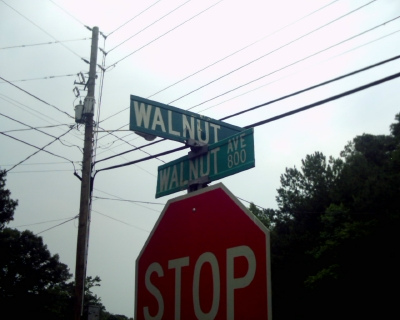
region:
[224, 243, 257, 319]
White P in STOP.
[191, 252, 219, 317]
White O in STOP.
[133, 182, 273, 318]
Red and white stop sign.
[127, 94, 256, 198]
Two green and white WALNUT signs.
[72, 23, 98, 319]
A tall brown wood sign.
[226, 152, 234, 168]
A white 8.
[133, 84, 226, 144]
this is a sign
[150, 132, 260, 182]
this is a sign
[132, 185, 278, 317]
this is a sign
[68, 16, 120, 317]
this is an electricity post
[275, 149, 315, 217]
the is a tree branch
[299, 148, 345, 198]
the is a tree branch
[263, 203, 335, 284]
the is a tree branch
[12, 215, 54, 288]
the is a tree branch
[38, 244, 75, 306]
the is a tree branch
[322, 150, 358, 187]
the is a tree branch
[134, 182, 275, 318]
An octagon red and white stop sign.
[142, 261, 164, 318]
White S in STOP.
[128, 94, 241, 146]
Green and white top sign that says WALNUT.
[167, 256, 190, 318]
White T in STOP.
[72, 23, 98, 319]
A tall brown power pole.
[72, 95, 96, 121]
Transformer buckets up on a brown pole.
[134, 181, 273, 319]
A white and red octagon stop sign.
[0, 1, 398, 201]
Blue and white sky.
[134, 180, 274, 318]
red and white metal stop sign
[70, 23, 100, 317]
wooden power line pole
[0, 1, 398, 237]
high power lines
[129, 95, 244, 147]
green and white street sign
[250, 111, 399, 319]
top of a tall green tree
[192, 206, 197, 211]
small silver bolt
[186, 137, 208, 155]
silver metal sign hardware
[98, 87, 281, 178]
the street sign is green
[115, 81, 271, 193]
the street sign is green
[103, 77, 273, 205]
the street sign is green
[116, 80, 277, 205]
the street sign is green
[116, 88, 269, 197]
the street sign is green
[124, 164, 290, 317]
a red STOP sign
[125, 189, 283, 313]
a red STOP sign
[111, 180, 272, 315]
a red STOP sign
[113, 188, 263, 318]
a red STOP sign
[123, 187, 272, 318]
a red STOP sign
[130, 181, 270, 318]
A red stop sign under power lines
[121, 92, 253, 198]
Green signs on top of a stop sign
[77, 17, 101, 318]
A tall telephone pole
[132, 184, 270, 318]
a red stop sign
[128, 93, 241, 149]
a green street name sign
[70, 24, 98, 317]
a wooden telephone pole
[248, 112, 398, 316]
a group of green trees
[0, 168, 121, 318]
a group of green trees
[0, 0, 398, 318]
a cloudy overcast sky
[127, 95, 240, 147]
WALNUT street sign